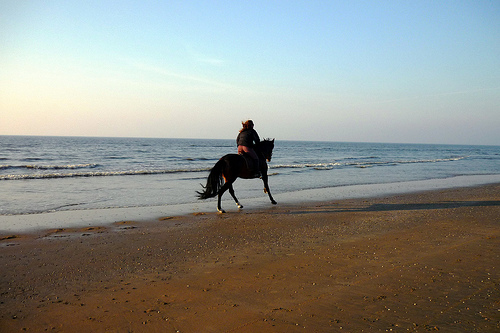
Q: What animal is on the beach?
A: Horse.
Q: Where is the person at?
A: On back of horse.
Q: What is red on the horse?
A: Pants.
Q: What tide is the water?
A: Low tide.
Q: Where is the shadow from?
A: Horse.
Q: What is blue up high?
A: Sky.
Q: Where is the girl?
A: On a horse.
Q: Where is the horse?
A: On sand.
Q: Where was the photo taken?
A: Beach.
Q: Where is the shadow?
A: On sand.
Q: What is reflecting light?
A: Water.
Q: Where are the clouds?
A: Sky.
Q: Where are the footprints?
A: Behind the horse.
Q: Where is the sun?
A: On the left.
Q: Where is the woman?
A: On horse.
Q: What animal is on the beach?
A: Horse.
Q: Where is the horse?
A: On the beach.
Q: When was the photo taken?
A: Daytime.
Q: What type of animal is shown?
A: Horse.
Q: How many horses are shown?
A: One.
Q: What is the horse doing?
A: Running.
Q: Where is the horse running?
A: Beach.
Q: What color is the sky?
A: Blue.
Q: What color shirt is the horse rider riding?
A: Black.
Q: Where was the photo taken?
A: On the beach.